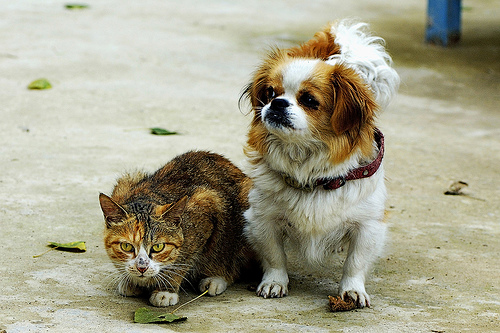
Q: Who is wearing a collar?
A: The dog.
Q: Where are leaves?
A: On the ground.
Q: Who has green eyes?
A: The cat.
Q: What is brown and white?
A: A dog.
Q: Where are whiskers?
A: On cat's face.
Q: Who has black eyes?
A: A dog.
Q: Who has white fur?
A: Dog.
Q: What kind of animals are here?
A: Dog and cat.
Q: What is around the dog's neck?
A: A collar.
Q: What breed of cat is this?
A: Calico.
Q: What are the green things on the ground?
A: Leaves.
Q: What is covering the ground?
A: Dirt.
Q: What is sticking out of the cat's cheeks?
A: Whiskers.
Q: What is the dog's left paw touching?
A: A leaf.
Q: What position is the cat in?
A: Crouching.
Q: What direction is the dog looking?
A: Left.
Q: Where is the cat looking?
A: Toward the camera.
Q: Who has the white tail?
A: The dog.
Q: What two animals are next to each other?
A: Dog and a cat.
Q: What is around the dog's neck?
A: A collar.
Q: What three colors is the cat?
A: White, orange and brown.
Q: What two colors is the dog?
A: Brown and white.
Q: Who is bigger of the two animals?
A: The dog.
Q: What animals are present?
A: Dog and cat.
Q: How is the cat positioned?
A: Crouching.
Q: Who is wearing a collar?
A: Dog.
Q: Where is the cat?
A: Left.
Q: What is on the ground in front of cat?
A: Leaf.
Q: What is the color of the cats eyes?
A: Green.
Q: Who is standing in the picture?
A: Dog.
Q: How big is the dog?
A: Small.